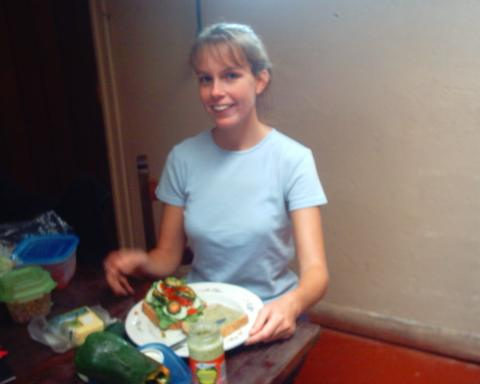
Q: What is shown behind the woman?
A: A wall.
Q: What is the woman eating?
A: A sandwich.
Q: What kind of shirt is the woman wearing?
A: A t-shirt.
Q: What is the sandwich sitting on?
A: A plate.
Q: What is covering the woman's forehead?
A: Bangs.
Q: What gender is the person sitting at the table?
A: A woman.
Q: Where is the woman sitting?
A: Dinner table.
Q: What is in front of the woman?
A: Food.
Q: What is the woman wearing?
A: Blue shirt.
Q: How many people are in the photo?
A: 1.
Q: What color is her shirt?
A: Light blue.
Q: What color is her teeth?
A: White.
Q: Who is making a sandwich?
A: The woman.